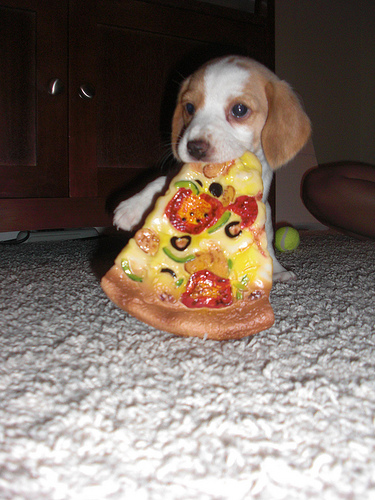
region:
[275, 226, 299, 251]
green tennis ball on the floor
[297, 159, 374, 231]
folded leg on person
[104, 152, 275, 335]
large piece of pizza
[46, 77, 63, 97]
round silver knob on cabinet door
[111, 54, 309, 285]
white and brown puppy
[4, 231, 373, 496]
white carpet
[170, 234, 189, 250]
sliced black olive on the pizza slice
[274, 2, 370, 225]
part of a white wall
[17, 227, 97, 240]
gray power strip under the cabinet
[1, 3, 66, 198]
door of cabinet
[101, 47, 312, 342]
this is a dog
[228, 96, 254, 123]
an eye of a dog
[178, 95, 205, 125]
an eye of a dog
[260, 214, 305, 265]
this is a ball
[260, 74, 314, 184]
an ear of a dog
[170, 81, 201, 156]
an ear of a dog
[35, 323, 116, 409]
some carpet on the ground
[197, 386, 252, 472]
some carpet on the ground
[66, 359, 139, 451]
some carpet on the ground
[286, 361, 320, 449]
some carpet on the ground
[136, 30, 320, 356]
This is a puppy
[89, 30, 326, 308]
Puppy is white and brown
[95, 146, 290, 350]
This is a toy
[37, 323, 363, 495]
Carpet is white brown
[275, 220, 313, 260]
Tennis ball in corner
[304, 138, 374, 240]
Someone's bare leg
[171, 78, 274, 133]
Dog is not looking at the camera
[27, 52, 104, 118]
Knobs on the cabinet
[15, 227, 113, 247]
Electricity on the ground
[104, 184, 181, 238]
Paw in the air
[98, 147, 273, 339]
A dog toy shaped like a pizza.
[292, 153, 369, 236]
A person's leg while sitting.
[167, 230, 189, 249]
A olive on the dog toy.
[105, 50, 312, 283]
A brown and white puppy.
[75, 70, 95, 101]
A knob on a cabinet.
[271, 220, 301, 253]
A yellow tennis ball.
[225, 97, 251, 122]
The eye of a puppy.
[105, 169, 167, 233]
The paw of a puppy.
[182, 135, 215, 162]
The nose of a puppy.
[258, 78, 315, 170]
A ear of a puppy.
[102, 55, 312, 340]
a puppy eating a slice of pizza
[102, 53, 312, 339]
a puppy with a slice of pizza in its mouth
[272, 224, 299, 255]
a yellow tennis ball on a carpet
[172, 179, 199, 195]
a bit of green pepper on a pizza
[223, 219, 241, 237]
a slice of black olive on a pizza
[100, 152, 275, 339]
a slice of pizza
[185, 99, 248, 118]
a puppy with blue eyes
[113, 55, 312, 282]
a white and brown puppy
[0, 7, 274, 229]
a wooden cabinet on a carpet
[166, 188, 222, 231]
a slice of tomato on a pizza